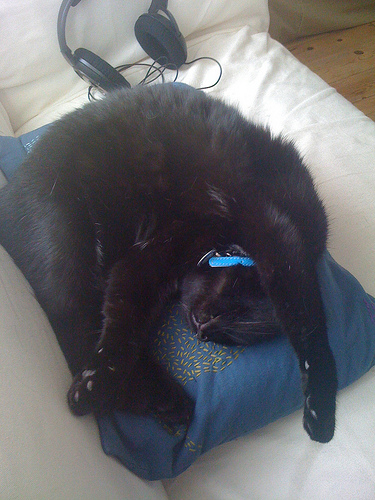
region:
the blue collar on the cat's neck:
[196, 245, 257, 272]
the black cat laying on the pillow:
[20, 82, 346, 432]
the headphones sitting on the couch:
[55, 0, 221, 96]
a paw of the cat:
[65, 354, 107, 410]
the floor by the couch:
[288, 21, 374, 128]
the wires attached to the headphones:
[87, 53, 227, 101]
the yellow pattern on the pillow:
[151, 316, 231, 388]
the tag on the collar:
[193, 246, 213, 269]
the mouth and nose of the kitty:
[188, 308, 222, 344]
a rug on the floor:
[270, 1, 374, 38]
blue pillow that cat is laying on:
[198, 375, 269, 422]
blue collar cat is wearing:
[199, 249, 262, 268]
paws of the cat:
[63, 362, 117, 423]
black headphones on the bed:
[45, 5, 240, 93]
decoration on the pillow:
[166, 347, 243, 373]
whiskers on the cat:
[216, 318, 263, 341]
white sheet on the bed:
[233, 40, 286, 94]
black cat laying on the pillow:
[9, 80, 351, 442]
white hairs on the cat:
[124, 221, 165, 252]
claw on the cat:
[300, 358, 315, 373]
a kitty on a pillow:
[9, 80, 373, 444]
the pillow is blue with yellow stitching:
[4, 124, 369, 482]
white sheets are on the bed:
[8, 2, 371, 496]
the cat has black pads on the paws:
[65, 338, 326, 444]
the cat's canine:
[194, 300, 225, 340]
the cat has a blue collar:
[194, 240, 254, 272]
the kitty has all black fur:
[0, 83, 373, 445]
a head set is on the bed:
[57, 0, 223, 100]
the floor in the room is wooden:
[292, 23, 374, 114]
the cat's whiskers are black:
[167, 292, 272, 350]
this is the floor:
[321, 38, 361, 61]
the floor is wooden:
[333, 55, 355, 74]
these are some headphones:
[51, 0, 223, 84]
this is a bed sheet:
[257, 66, 288, 106]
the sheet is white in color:
[328, 128, 362, 177]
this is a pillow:
[221, 347, 289, 415]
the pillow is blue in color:
[218, 375, 270, 411]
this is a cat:
[13, 81, 348, 447]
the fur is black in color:
[98, 121, 189, 200]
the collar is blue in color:
[212, 258, 250, 267]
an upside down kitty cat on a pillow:
[8, 80, 337, 444]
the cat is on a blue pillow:
[12, 96, 340, 487]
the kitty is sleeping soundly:
[56, 216, 343, 440]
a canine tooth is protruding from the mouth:
[200, 307, 222, 332]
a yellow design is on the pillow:
[151, 310, 247, 447]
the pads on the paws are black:
[56, 343, 338, 446]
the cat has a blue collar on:
[197, 238, 256, 273]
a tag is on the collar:
[192, 247, 217, 268]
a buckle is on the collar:
[218, 245, 242, 271]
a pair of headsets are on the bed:
[52, 1, 223, 101]